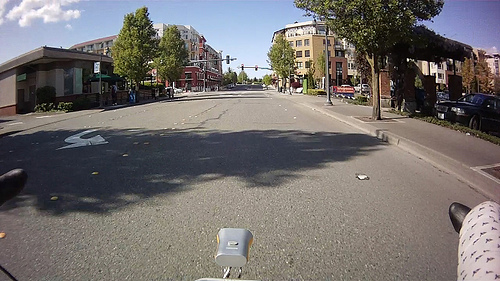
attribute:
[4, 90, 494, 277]
street — empty, road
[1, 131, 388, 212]
shadow — large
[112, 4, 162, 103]
tree — green, leafy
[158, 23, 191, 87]
tree — green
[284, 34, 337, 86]
building — beige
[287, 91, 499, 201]
sidewalk — empty, cement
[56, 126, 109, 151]
arrow — painted, white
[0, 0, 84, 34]
cloud — puffy, fluffy, white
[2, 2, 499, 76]
sky — blue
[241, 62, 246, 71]
signal — red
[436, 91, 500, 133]
truck — black, parked, dark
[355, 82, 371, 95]
hatchback — white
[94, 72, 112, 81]
awning — green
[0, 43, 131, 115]
building — single-story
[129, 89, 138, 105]
trashcan — blue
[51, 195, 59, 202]
reflector — yellow, bump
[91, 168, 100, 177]
reflector — yellow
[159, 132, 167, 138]
reflector — yellow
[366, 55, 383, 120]
trunk — brown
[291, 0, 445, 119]
tree — green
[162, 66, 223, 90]
building — brick